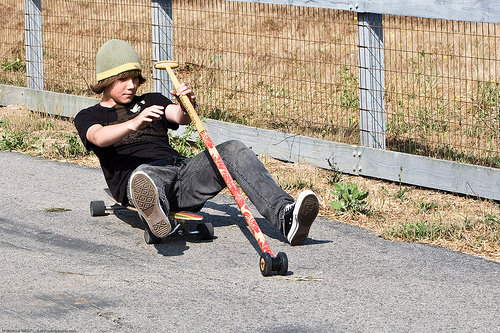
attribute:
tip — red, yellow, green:
[171, 207, 208, 224]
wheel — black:
[88, 197, 111, 219]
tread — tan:
[132, 175, 158, 217]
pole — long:
[153, 59, 284, 257]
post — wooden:
[354, 12, 390, 152]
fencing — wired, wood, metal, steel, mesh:
[1, 1, 498, 173]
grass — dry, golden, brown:
[0, 3, 500, 159]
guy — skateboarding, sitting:
[73, 35, 321, 248]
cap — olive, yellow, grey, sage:
[93, 35, 143, 83]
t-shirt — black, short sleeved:
[73, 90, 188, 211]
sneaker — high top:
[278, 188, 322, 248]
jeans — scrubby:
[129, 140, 297, 239]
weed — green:
[326, 176, 374, 220]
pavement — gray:
[2, 152, 497, 333]